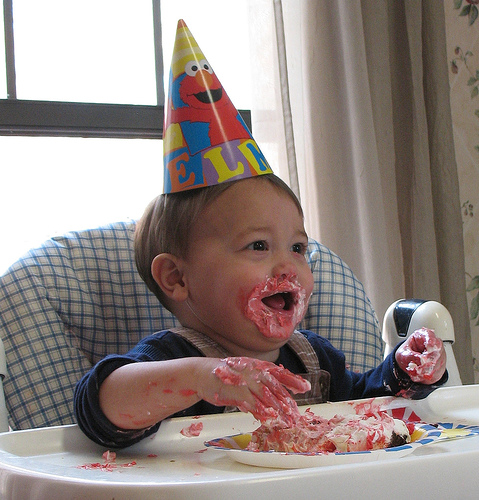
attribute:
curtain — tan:
[305, 4, 479, 387]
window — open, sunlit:
[1, 2, 321, 267]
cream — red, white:
[237, 279, 305, 335]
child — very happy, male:
[74, 172, 447, 448]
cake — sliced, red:
[257, 403, 411, 454]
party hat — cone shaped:
[154, 16, 277, 197]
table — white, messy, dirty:
[0, 377, 477, 499]